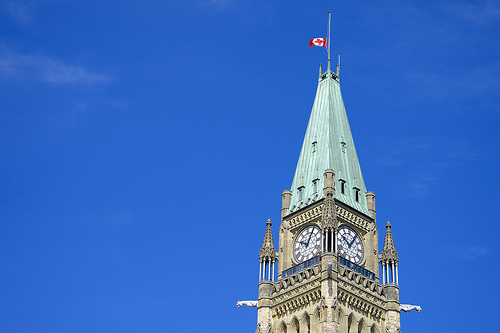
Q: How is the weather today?
A: It is sunny.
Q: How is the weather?
A: It is sunny.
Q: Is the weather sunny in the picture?
A: Yes, it is sunny.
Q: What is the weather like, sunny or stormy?
A: It is sunny.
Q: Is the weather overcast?
A: No, it is sunny.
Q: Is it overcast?
A: No, it is sunny.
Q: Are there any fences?
A: No, there are no fences.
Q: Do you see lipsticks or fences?
A: No, there are no fences or lipsticks.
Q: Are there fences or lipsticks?
A: No, there are no fences or lipsticks.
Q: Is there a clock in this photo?
A: Yes, there is a clock.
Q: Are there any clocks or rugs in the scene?
A: Yes, there is a clock.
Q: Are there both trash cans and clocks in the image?
A: No, there is a clock but no trash cans.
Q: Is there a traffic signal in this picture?
A: No, there are no traffic lights.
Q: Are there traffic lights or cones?
A: No, there are no traffic lights or cones.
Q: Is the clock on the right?
A: Yes, the clock is on the right of the image.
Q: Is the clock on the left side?
A: No, the clock is on the right of the image.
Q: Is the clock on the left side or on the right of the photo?
A: The clock is on the right of the image.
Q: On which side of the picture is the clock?
A: The clock is on the right of the image.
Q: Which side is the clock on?
A: The clock is on the right of the image.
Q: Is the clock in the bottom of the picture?
A: Yes, the clock is in the bottom of the image.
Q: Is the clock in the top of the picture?
A: No, the clock is in the bottom of the image.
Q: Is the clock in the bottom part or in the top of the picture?
A: The clock is in the bottom of the image.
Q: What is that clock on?
A: The clock is on the building.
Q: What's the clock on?
A: The clock is on the building.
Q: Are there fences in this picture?
A: No, there are no fences.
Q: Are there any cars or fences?
A: No, there are no fences or cars.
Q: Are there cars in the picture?
A: No, there are no cars.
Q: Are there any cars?
A: No, there are no cars.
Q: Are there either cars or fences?
A: No, there are no cars or fences.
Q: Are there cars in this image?
A: No, there are no cars.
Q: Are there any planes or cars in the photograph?
A: No, there are no cars or planes.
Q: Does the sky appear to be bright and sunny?
A: Yes, the sky is bright and sunny.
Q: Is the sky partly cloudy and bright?
A: No, the sky is bright but sunny.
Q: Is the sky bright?
A: Yes, the sky is bright.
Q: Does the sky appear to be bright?
A: Yes, the sky is bright.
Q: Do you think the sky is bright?
A: Yes, the sky is bright.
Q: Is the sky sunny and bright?
A: Yes, the sky is sunny and bright.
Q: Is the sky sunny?
A: Yes, the sky is sunny.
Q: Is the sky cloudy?
A: No, the sky is sunny.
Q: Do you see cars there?
A: No, there are no cars.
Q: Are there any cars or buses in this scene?
A: No, there are no cars or buses.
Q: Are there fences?
A: No, there are no fences.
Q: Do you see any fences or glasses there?
A: No, there are no fences or glasses.